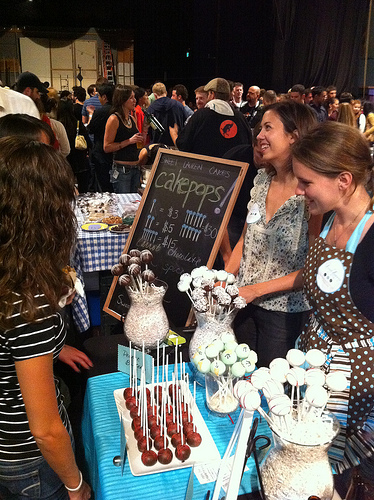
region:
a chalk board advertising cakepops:
[101, 147, 250, 324]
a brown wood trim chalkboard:
[101, 147, 247, 328]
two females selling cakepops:
[220, 100, 372, 267]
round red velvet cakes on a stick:
[120, 336, 199, 464]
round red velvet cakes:
[121, 383, 199, 463]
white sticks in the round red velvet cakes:
[129, 338, 196, 452]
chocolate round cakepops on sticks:
[109, 248, 154, 287]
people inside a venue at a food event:
[1, 69, 373, 497]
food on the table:
[81, 192, 111, 270]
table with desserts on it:
[84, 358, 320, 495]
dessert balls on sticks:
[125, 346, 199, 463]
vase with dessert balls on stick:
[229, 351, 343, 493]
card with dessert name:
[108, 341, 157, 383]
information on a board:
[146, 169, 194, 258]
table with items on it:
[66, 182, 147, 260]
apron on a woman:
[303, 210, 367, 427]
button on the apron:
[318, 245, 346, 296]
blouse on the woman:
[238, 169, 313, 317]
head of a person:
[0, 142, 91, 250]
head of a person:
[279, 127, 367, 221]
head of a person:
[234, 71, 315, 175]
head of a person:
[203, 61, 244, 109]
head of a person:
[146, 77, 166, 106]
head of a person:
[17, 63, 52, 102]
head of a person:
[308, 85, 328, 103]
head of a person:
[284, 73, 314, 100]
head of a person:
[261, 84, 278, 104]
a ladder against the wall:
[100, 47, 113, 80]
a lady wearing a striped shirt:
[2, 224, 90, 496]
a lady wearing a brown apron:
[302, 128, 364, 454]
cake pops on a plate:
[117, 368, 211, 457]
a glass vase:
[263, 408, 328, 498]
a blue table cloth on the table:
[86, 369, 256, 497]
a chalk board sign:
[106, 149, 249, 327]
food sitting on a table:
[80, 192, 129, 233]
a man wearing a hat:
[189, 80, 244, 138]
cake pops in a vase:
[178, 268, 233, 341]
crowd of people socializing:
[1, 64, 371, 474]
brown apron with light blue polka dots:
[293, 219, 373, 463]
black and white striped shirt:
[2, 258, 78, 465]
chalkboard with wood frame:
[107, 139, 243, 338]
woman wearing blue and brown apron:
[288, 131, 372, 487]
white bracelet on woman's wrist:
[63, 474, 85, 493]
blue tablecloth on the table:
[61, 361, 303, 497]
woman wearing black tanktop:
[98, 83, 140, 189]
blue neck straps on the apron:
[312, 180, 372, 240]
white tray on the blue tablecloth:
[111, 381, 223, 471]